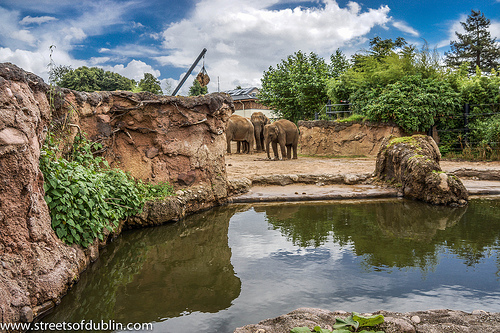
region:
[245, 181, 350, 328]
the water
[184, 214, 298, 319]
the water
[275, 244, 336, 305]
the water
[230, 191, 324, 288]
the water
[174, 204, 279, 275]
the water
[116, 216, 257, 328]
a reflection on water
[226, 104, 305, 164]
A herd of elephants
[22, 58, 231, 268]
A brown dirt cliff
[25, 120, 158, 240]
Green vine on the side of the cliff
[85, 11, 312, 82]
Bright blue sky with clouds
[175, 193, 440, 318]
The water is green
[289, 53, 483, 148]
Dense foliage behind the fence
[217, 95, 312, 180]
The elephants are brown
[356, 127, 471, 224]
Rock near the waters edge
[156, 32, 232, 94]
Pole with brown bag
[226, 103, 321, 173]
The elephants are standing on dirt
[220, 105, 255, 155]
a brown elephant standing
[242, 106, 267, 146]
a brown elephant standing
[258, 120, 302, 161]
a brown elephant standing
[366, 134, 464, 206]
a large boulder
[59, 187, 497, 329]
a large pool of water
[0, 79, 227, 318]
a brown cliff side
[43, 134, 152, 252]
a green bush vine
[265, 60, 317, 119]
a large tree in distance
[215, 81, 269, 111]
a large structure in distance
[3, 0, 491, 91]
a blue cloudy sky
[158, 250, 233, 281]
the water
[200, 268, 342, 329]
the water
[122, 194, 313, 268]
the water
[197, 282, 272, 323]
the water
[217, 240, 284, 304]
the water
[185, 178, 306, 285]
the water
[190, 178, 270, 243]
the water